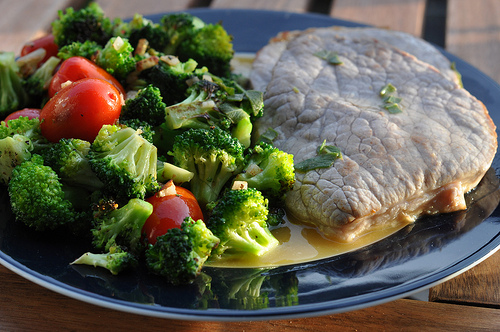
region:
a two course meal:
[51, 28, 461, 315]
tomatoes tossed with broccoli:
[40, 56, 250, 284]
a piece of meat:
[205, 28, 479, 253]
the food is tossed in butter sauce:
[124, 68, 412, 296]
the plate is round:
[19, 14, 498, 286]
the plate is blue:
[263, 234, 382, 329]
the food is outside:
[34, 13, 491, 260]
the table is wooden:
[429, 253, 490, 311]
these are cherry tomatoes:
[27, 34, 196, 221]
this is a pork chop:
[204, 3, 495, 298]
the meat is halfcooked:
[253, 52, 407, 162]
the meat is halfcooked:
[302, 87, 433, 178]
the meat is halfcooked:
[317, 20, 357, 77]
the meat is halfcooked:
[290, 130, 430, 228]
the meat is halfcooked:
[307, 101, 398, 209]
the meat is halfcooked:
[330, 107, 470, 274]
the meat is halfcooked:
[326, 90, 388, 150]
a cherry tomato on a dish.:
[29, 51, 162, 148]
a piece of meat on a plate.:
[230, 31, 497, 248]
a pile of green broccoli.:
[0, 0, 281, 304]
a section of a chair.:
[407, 5, 452, 60]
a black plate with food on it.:
[0, 1, 496, 320]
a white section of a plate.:
[178, 186, 423, 269]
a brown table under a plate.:
[415, 3, 495, 73]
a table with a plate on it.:
[0, 1, 132, 43]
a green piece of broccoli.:
[208, 175, 293, 277]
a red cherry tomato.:
[141, 180, 216, 253]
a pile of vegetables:
[8, 22, 239, 241]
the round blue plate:
[2, 10, 499, 316]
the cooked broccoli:
[135, 66, 238, 175]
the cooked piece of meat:
[266, 30, 469, 216]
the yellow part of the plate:
[280, 230, 316, 256]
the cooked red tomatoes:
[40, 60, 117, 120]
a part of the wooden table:
[436, 282, 491, 327]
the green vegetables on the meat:
[370, 71, 405, 121]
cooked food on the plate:
[9, 17, 464, 215]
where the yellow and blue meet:
[281, 237, 325, 298]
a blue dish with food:
[2, 2, 497, 327]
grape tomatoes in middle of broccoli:
[7, 25, 192, 240]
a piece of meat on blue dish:
[241, 15, 496, 245]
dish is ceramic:
[0, 1, 495, 321]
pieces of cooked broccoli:
[136, 5, 266, 170]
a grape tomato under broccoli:
[0, 95, 40, 142]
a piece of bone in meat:
[424, 174, 471, 221]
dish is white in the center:
[127, 205, 499, 317]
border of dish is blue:
[203, 253, 486, 328]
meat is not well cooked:
[250, 16, 497, 238]